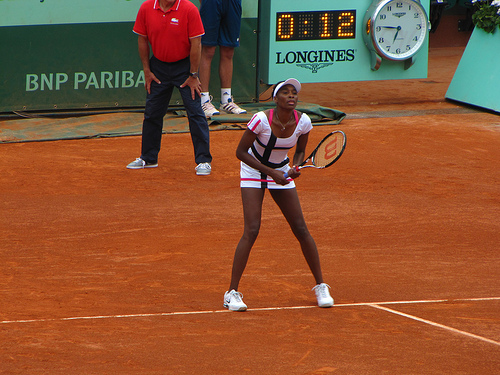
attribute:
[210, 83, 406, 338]
woman — playing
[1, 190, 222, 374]
court — orange, outdoors, clay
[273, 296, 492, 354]
lines — white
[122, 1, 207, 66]
shirt — red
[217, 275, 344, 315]
shoes — white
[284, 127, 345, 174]
racket — wilson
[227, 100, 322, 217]
outfit — white, red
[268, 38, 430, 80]
advert — turquoise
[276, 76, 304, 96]
visor — white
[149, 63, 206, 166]
pants — black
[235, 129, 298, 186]
stripes — pink